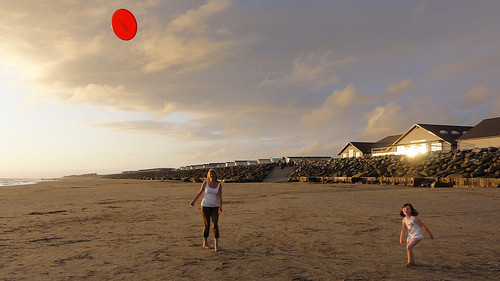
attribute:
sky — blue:
[325, 35, 423, 92]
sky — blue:
[263, 30, 478, 99]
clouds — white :
[4, 3, 384, 130]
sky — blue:
[4, 2, 494, 175]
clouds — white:
[25, 29, 102, 111]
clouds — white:
[159, 14, 343, 116]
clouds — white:
[342, 14, 484, 104]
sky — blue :
[1, 4, 493, 149]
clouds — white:
[3, 2, 499, 155]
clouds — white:
[64, 8, 383, 148]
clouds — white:
[153, 8, 281, 136]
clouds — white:
[80, 52, 193, 125]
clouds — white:
[94, 74, 237, 132]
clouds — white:
[160, 58, 288, 88]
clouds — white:
[190, 45, 294, 137]